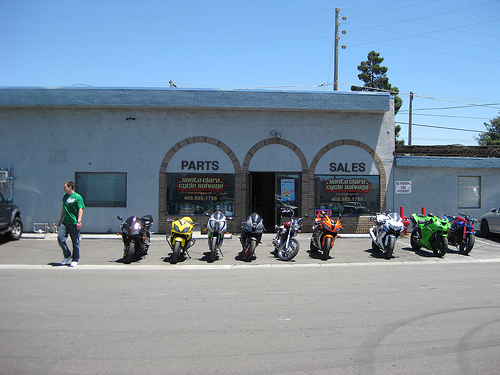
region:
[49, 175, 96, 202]
Man has brown hair.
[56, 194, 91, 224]
Man wearing green shirt.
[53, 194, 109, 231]
Man wearing t-shirt.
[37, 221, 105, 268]
Man wearing blue jeans.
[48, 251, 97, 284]
Man wearing white shoes.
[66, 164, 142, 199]
Window on front of building.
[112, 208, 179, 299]
Black bike parked in front of store.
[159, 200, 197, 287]
Yellow bike parked in front of store.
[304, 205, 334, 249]
Orange bike parked in front of store.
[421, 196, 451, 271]
Green bike parked in front of store.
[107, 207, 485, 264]
nine motorcycles in a row.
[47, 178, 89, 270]
man wearing green t-shirt and jeans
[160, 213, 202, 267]
bright yellow parked motorcycles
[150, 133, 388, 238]
motorcycle sales and parts store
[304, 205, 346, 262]
orange motorcycle for sale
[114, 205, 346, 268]
6 different bikes for sale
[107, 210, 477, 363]
road in front of parted motorcycles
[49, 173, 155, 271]
man walking away from motorcycle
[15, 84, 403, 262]
old building that sell bikes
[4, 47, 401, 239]
tree behind old building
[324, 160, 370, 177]
Black "Sales" sign on the building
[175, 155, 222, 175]
Black "Parts" sign on the building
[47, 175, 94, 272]
Person in a green shirt and jeans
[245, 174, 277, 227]
Dark door entrance to the building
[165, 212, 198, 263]
Yellow and black motorcycle outside the building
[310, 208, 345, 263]
Orange and black motorcycle outside the building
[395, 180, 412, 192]
White sign on the building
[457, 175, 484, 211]
Window with blinds drawn inside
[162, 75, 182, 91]
Object on top of the building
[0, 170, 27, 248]
Front corner of a car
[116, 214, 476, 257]
Motorcycles parked on a street.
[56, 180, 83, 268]
A man standing on the side of a street.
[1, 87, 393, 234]
A motorcycle parts and sales store.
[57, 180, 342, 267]
A man standing next to a group of motorcycles.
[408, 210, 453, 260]
A lime green motorcycle.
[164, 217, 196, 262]
A yellow motorcycle.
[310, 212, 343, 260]
An orange motorcycle parked on the street.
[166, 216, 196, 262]
A yellow motorcyle parked.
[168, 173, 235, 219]
The front window of a motorcycle shop.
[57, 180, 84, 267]
A man in a green shirt and jeans.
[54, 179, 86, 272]
Man wearing a green shirt and blue jeans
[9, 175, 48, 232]
Reflection of car on building wall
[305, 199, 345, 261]
Orange motorcycle parked in front of store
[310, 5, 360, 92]
Telephone pole behind parts store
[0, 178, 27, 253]
Dark grey car parked next to auto parts store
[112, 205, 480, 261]
Nine motorcycles parked in a row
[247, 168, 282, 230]
Opened door in auto parts store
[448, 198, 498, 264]
White automobile parked next to a red and blue motorcycle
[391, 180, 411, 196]
Red and white sign on building wall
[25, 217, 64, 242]
Pipes sticking out of building wall